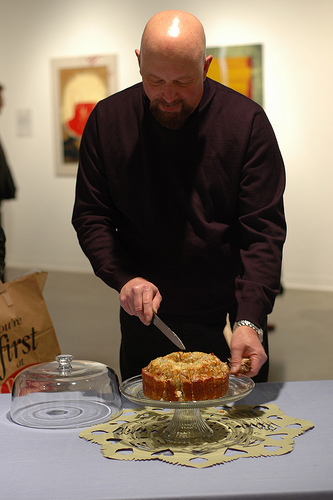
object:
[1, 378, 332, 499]
table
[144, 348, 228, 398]
cake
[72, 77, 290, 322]
shirt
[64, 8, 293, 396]
man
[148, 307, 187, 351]
knife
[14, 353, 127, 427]
glass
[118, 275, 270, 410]
hands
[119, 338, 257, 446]
dish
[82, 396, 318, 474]
place mat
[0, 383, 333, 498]
tablecloth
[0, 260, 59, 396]
shopping bag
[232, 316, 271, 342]
watch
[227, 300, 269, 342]
wrist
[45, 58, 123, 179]
painting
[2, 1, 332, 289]
wall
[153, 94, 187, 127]
beard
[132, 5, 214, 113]
head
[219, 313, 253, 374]
napkin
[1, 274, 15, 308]
handles